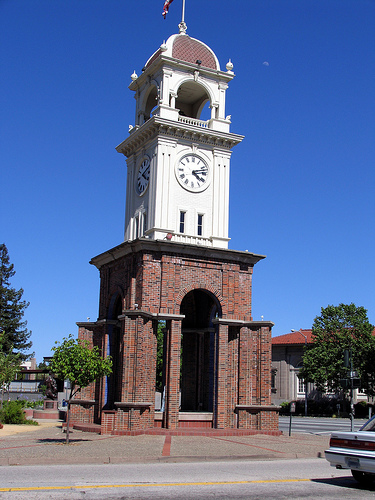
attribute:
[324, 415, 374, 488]
car — white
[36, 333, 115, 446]
tree — small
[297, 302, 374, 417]
tree — small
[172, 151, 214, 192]
clock face — round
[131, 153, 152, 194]
clock face — round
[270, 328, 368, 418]
building — small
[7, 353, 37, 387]
building — small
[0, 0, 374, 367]
sky — bright blue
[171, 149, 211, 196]
clock — round, white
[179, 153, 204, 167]
numerals — roman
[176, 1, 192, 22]
pole — metal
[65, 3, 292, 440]
tower — clock, old clock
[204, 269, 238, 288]
brick — red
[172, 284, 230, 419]
doorway — arched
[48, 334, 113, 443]
bush — green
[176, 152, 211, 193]
clock — white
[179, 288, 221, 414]
opening — arched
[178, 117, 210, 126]
railing — white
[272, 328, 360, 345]
roof — red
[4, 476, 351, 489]
line — yellow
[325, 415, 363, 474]
car — white, compact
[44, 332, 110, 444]
tree — small, deciduous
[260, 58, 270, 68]
moon — showing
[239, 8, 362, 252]
sky — clear, daytime